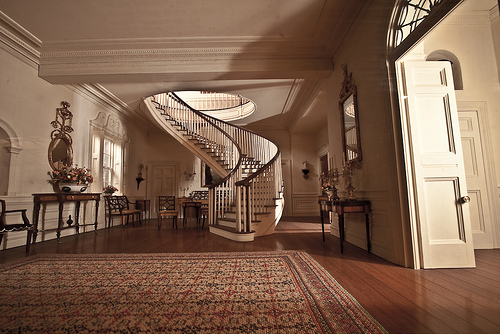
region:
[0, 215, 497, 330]
area rug on brown wooden floor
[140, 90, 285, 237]
white and brown spiral staircase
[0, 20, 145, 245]
large window on white painted wall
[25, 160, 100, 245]
pink potted flowers on wooden table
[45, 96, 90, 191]
decorative mirror above flowers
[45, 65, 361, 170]
decorative mirror across from decorative mirror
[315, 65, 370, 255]
decorative mirror hanging above wooden table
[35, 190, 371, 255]
brown wooden table across from brown wooden table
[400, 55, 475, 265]
metal door knob on white painted door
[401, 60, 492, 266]
white painted door behind white painted door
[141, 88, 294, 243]
ornate opulent spiral staircase with wood banister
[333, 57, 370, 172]
large ornate metal rectangular mirror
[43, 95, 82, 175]
large ornate round mirror with fancy metal frame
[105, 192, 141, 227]
fancy wooden chairs with cream-colored upholstery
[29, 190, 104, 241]
ornate skinny dark wood console table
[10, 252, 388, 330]
geometric-patterned earth-toned persian rug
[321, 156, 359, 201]
ornate silver candelabra with cream-colored candles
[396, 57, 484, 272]
large sturdy white-painted wooden door with glass handle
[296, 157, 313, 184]
large wall sconce with light-colored candle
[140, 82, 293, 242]
beautiful imposing spiral staircase with dark wood trim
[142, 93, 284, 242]
white curving staircase with dark railing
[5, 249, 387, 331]
very large rug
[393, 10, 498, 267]
an open doorway on the right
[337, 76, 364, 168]
rectangle mirrow on right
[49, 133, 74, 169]
oval shaped mirror on left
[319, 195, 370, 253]
table under rectangle mirror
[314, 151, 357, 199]
candelabras on table under rectangle mirror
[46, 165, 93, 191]
bowl with flowers under oval mirror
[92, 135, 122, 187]
large window on left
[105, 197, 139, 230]
bench underneath the window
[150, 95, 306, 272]
the stairway is curvy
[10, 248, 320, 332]
the rug is big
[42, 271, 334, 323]
the rug is colorful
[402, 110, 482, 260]
the door is white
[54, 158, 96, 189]
the flowers is on the table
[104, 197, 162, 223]
a long bench is in the hall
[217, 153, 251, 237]
the steps is white brown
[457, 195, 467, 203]
door knob is gold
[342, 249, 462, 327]
the floor is shiney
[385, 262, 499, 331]
the floor is wooden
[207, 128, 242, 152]
A spiral staircase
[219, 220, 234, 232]
The stairs to the top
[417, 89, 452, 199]
A large door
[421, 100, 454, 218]
An open door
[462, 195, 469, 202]
A knob on the door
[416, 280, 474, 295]
A wooden floor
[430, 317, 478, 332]
Shadow on the floor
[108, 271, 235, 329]
A rug on the floor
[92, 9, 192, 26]
The ceiling on the building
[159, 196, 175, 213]
A chair on the floor